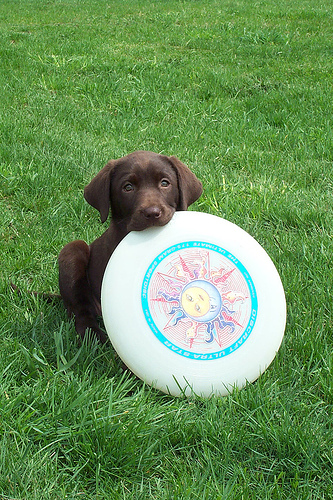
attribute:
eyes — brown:
[119, 179, 177, 193]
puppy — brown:
[56, 149, 203, 346]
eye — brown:
[119, 180, 136, 193]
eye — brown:
[158, 177, 173, 189]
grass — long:
[0, 0, 331, 499]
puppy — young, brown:
[47, 151, 205, 341]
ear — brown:
[82, 160, 117, 222]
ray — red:
[175, 254, 194, 277]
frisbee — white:
[92, 209, 289, 394]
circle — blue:
[140, 239, 255, 360]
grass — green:
[87, 0, 267, 156]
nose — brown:
[145, 206, 160, 219]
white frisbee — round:
[97, 207, 291, 400]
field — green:
[2, 0, 322, 497]